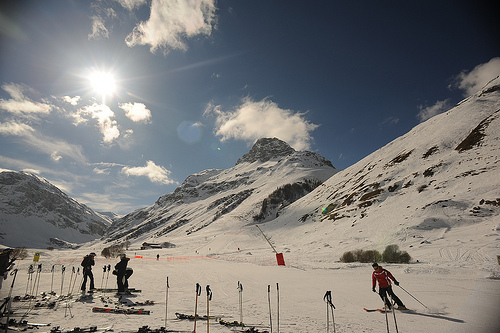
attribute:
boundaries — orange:
[95, 248, 258, 261]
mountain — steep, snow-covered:
[61, 131, 340, 246]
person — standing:
[369, 262, 412, 312]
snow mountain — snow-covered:
[90, 140, 332, 242]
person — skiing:
[369, 254, 410, 315]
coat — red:
[369, 267, 396, 283]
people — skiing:
[73, 247, 104, 300]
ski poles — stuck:
[389, 273, 446, 321]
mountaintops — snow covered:
[98, 127, 425, 297]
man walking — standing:
[63, 233, 141, 305]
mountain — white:
[0, 165, 129, 244]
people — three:
[113, 255, 132, 287]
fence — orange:
[109, 250, 199, 263]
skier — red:
[365, 261, 412, 311]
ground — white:
[296, 49, 351, 96]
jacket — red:
[367, 266, 392, 293]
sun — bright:
[63, 57, 138, 134]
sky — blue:
[0, 3, 500, 220]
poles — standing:
[397, 288, 442, 316]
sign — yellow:
[32, 249, 44, 265]